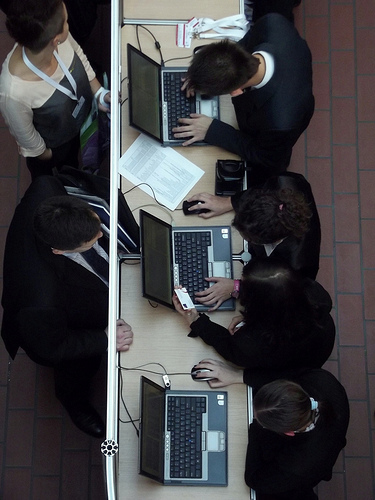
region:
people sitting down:
[25, 23, 367, 476]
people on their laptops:
[126, 59, 346, 465]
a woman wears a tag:
[39, 55, 90, 134]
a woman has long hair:
[231, 188, 302, 231]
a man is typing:
[173, 65, 210, 140]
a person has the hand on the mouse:
[195, 352, 232, 388]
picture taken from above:
[43, 37, 371, 490]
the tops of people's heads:
[197, 75, 351, 452]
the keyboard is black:
[176, 403, 192, 466]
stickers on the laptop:
[213, 390, 225, 406]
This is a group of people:
[8, 19, 359, 423]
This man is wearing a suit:
[223, 33, 310, 162]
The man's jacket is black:
[244, 33, 316, 171]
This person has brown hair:
[257, 379, 315, 430]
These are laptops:
[130, 204, 232, 487]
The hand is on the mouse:
[171, 345, 237, 391]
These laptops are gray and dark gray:
[147, 218, 233, 311]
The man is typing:
[165, 77, 218, 146]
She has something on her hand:
[69, 70, 135, 128]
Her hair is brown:
[12, 6, 83, 86]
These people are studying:
[19, 16, 325, 367]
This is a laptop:
[129, 368, 259, 498]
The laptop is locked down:
[155, 364, 181, 392]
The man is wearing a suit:
[12, 197, 113, 378]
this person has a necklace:
[13, 26, 97, 132]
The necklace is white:
[24, 52, 97, 122]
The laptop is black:
[144, 373, 242, 497]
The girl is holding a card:
[157, 278, 238, 347]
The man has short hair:
[27, 194, 97, 267]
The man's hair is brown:
[29, 192, 105, 271]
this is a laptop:
[122, 42, 176, 129]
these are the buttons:
[171, 396, 193, 472]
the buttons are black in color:
[177, 414, 194, 443]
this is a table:
[145, 326, 168, 348]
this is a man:
[180, 32, 282, 127]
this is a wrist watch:
[234, 276, 240, 304]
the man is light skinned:
[190, 116, 205, 136]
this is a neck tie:
[91, 252, 109, 269]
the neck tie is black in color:
[89, 253, 106, 263]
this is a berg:
[70, 88, 97, 123]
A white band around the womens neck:
[23, 51, 85, 119]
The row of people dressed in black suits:
[232, 0, 342, 498]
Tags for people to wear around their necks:
[163, 9, 249, 49]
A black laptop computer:
[136, 380, 227, 486]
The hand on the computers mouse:
[191, 357, 225, 389]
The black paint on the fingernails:
[186, 358, 206, 382]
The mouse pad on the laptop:
[207, 431, 226, 456]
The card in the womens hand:
[171, 286, 197, 311]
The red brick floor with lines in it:
[321, 5, 374, 239]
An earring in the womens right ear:
[51, 32, 62, 48]